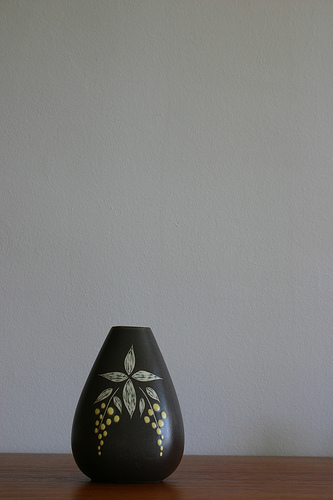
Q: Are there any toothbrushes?
A: No, there are no toothbrushes.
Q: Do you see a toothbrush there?
A: No, there are no toothbrushes.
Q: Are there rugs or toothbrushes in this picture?
A: No, there are no toothbrushes or rugs.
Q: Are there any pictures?
A: No, there are no pictures.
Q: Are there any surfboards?
A: No, there are no surfboards.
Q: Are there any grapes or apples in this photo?
A: Yes, there are grapes.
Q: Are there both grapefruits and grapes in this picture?
A: No, there are grapes but no grapefruits.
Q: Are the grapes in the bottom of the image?
A: Yes, the grapes are in the bottom of the image.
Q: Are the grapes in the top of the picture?
A: No, the grapes are in the bottom of the image.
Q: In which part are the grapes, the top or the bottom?
A: The grapes are in the bottom of the image.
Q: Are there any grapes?
A: Yes, there are grapes.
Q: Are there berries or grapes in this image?
A: Yes, there are grapes.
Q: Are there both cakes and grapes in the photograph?
A: No, there are grapes but no cakes.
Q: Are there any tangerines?
A: No, there are no tangerines.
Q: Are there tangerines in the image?
A: No, there are no tangerines.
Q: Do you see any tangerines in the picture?
A: No, there are no tangerines.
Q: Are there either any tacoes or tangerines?
A: No, there are no tangerines or tacoes.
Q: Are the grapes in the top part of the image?
A: No, the grapes are in the bottom of the image.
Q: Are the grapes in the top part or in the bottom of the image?
A: The grapes are in the bottom of the image.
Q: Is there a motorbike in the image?
A: No, there are no motorcycles.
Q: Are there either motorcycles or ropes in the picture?
A: No, there are no motorcycles or ropes.